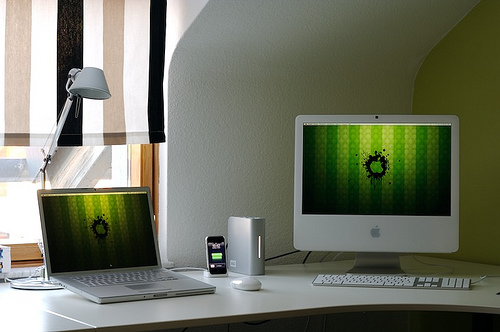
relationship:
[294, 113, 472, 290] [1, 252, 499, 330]
computer on desk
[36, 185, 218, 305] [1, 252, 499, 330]
laptop on desk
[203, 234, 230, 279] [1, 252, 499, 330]
cell phone on desk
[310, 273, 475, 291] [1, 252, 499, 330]
keyboard on desk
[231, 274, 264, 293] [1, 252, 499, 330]
mouse on desk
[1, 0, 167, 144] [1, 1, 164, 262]
curtain in front of window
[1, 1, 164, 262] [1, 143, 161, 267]
window has frame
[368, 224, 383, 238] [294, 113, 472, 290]
logo on computer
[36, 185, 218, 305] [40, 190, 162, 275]
laptop has monitor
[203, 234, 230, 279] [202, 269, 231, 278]
cell phone on charger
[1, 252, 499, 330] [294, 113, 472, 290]
desk with apple product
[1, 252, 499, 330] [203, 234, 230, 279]
desk with apple product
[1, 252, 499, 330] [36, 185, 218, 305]
desk with apple product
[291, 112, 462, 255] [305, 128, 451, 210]
monitor has green background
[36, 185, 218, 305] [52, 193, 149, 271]
laptop with green background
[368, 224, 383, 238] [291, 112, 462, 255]
logo on monitor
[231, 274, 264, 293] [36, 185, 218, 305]
mouse next to laptop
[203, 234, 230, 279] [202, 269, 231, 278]
cell phone in charger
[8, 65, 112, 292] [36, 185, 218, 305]
desk lamp behind laptop